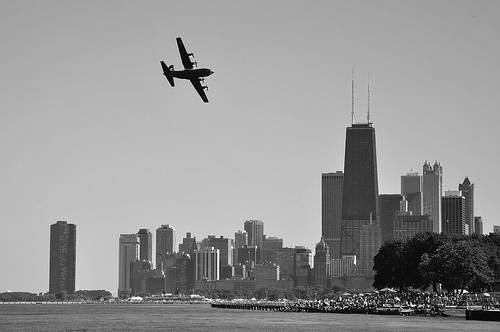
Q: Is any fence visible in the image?
A: No, there are no fences.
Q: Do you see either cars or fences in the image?
A: No, there are no fences or cars.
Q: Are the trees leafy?
A: Yes, the trees are leafy.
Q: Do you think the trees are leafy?
A: Yes, the trees are leafy.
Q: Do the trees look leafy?
A: Yes, the trees are leafy.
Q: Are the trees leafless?
A: No, the trees are leafy.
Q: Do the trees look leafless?
A: No, the trees are leafy.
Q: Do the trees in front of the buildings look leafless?
A: No, the trees are leafy.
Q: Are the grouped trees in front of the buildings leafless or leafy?
A: The trees are leafy.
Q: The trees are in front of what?
A: The trees are in front of the buildings.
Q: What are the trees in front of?
A: The trees are in front of the buildings.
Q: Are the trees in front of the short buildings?
A: Yes, the trees are in front of the buildings.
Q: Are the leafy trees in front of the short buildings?
A: Yes, the trees are in front of the buildings.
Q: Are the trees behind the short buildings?
A: No, the trees are in front of the buildings.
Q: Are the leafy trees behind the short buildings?
A: No, the trees are in front of the buildings.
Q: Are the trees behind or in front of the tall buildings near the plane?
A: The trees are in front of the buildings.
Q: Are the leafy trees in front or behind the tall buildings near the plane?
A: The trees are in front of the buildings.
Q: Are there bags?
A: No, there are no bags.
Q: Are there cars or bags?
A: No, there are no bags or cars.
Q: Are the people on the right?
A: Yes, the people are on the right of the image.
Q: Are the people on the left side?
A: No, the people are on the right of the image.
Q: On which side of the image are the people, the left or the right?
A: The people are on the right of the image.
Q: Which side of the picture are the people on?
A: The people are on the right of the image.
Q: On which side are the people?
A: The people are on the right of the image.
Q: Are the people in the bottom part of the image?
A: Yes, the people are in the bottom of the image.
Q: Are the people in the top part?
A: No, the people are in the bottom of the image.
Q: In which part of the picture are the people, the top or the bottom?
A: The people are in the bottom of the image.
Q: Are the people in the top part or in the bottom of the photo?
A: The people are in the bottom of the image.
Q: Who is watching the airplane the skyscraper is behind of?
A: The people are watching the airplane.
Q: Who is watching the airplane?
A: The people are watching the airplane.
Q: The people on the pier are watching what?
A: The people are watching the plane.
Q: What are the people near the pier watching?
A: The people are watching the plane.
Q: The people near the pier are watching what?
A: The people are watching the plane.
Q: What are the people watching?
A: The people are watching the plane.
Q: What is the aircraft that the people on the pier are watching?
A: The aircraft is an airplane.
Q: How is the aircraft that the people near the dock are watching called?
A: The aircraft is an airplane.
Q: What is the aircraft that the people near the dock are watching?
A: The aircraft is an airplane.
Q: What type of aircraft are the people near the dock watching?
A: The people are watching the airplane.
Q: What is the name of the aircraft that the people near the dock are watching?
A: The aircraft is an airplane.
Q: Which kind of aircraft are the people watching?
A: The people are watching the airplane.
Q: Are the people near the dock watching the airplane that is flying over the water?
A: Yes, the people are watching the airplane.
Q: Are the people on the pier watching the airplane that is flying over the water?
A: Yes, the people are watching the airplane.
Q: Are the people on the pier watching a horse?
A: No, the people are watching the airplane.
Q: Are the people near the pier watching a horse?
A: No, the people are watching the airplane.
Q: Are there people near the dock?
A: Yes, there are people near the dock.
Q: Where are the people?
A: The people are on the dock.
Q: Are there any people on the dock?
A: Yes, there are people on the dock.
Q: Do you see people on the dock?
A: Yes, there are people on the dock.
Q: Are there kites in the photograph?
A: No, there are no kites.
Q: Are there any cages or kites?
A: No, there are no kites or cages.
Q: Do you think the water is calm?
A: Yes, the water is calm.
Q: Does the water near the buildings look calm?
A: Yes, the water is calm.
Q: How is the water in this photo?
A: The water is calm.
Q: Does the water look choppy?
A: No, the water is calm.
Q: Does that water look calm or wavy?
A: The water is calm.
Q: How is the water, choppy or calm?
A: The water is calm.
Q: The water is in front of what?
A: The water is in front of the buildings.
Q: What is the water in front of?
A: The water is in front of the buildings.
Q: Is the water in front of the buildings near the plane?
A: Yes, the water is in front of the buildings.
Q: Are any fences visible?
A: No, there are no fences.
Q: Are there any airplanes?
A: Yes, there is an airplane.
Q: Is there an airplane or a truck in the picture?
A: Yes, there is an airplane.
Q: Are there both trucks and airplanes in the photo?
A: No, there is an airplane but no trucks.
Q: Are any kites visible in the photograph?
A: No, there are no kites.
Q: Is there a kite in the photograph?
A: No, there are no kites.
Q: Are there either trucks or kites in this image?
A: No, there are no kites or trucks.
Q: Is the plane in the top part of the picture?
A: Yes, the plane is in the top of the image.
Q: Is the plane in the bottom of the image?
A: No, the plane is in the top of the image.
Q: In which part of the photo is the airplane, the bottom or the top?
A: The airplane is in the top of the image.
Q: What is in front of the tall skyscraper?
A: The airplane is in front of the skyscraper.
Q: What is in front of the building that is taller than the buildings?
A: The airplane is in front of the skyscraper.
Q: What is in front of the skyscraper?
A: The airplane is in front of the skyscraper.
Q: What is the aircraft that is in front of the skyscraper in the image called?
A: The aircraft is an airplane.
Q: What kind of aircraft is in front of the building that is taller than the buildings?
A: The aircraft is an airplane.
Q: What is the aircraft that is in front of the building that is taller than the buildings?
A: The aircraft is an airplane.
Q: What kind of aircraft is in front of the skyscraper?
A: The aircraft is an airplane.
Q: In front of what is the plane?
A: The plane is in front of the skyscraper.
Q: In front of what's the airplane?
A: The plane is in front of the skyscraper.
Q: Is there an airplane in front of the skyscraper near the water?
A: Yes, there is an airplane in front of the skyscraper.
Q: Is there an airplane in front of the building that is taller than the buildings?
A: Yes, there is an airplane in front of the skyscraper.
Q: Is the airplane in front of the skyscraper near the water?
A: Yes, the airplane is in front of the skyscraper.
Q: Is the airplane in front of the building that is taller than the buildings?
A: Yes, the airplane is in front of the skyscraper.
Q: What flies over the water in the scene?
A: The airplane flies over the water.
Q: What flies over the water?
A: The airplane flies over the water.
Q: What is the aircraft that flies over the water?
A: The aircraft is an airplane.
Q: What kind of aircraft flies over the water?
A: The aircraft is an airplane.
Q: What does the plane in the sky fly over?
A: The plane flies over the water.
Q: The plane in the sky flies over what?
A: The plane flies over the water.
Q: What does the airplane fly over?
A: The plane flies over the water.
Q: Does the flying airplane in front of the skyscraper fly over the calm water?
A: Yes, the plane flies over the water.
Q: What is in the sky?
A: The plane is in the sky.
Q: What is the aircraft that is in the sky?
A: The aircraft is an airplane.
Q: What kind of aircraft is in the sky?
A: The aircraft is an airplane.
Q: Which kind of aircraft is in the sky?
A: The aircraft is an airplane.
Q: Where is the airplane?
A: The airplane is in the sky.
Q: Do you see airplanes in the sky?
A: Yes, there is an airplane in the sky.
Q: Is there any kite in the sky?
A: No, there is an airplane in the sky.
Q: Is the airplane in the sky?
A: Yes, the airplane is in the sky.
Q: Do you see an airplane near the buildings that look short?
A: Yes, there is an airplane near the buildings.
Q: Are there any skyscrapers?
A: Yes, there is a skyscraper.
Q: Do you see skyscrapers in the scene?
A: Yes, there is a skyscraper.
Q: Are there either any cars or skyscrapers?
A: Yes, there is a skyscraper.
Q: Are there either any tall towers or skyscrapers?
A: Yes, there is a tall skyscraper.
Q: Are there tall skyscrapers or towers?
A: Yes, there is a tall skyscraper.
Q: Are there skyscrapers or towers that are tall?
A: Yes, the skyscraper is tall.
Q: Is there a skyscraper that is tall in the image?
A: Yes, there is a tall skyscraper.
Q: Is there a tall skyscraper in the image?
A: Yes, there is a tall skyscraper.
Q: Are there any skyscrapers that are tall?
A: Yes, there is a skyscraper that is tall.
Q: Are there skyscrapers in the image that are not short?
A: Yes, there is a tall skyscraper.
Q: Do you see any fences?
A: No, there are no fences.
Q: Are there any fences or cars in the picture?
A: No, there are no fences or cars.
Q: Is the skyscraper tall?
A: Yes, the skyscraper is tall.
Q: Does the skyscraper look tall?
A: Yes, the skyscraper is tall.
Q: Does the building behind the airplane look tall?
A: Yes, the skyscraper is tall.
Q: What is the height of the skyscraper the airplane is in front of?
A: The skyscraper is tall.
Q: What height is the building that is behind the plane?
A: The skyscraper is tall.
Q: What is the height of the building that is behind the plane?
A: The skyscraper is tall.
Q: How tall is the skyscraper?
A: The skyscraper is tall.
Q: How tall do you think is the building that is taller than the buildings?
A: The skyscraper is tall.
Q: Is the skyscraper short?
A: No, the skyscraper is tall.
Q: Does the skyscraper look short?
A: No, the skyscraper is tall.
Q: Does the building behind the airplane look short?
A: No, the skyscraper is tall.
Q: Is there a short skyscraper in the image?
A: No, there is a skyscraper but it is tall.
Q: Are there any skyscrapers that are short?
A: No, there is a skyscraper but it is tall.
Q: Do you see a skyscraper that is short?
A: No, there is a skyscraper but it is tall.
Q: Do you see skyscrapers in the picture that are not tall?
A: No, there is a skyscraper but it is tall.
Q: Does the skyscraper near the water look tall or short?
A: The skyscraper is tall.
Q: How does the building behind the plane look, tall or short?
A: The skyscraper is tall.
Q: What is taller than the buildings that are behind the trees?
A: The skyscraper is taller than the buildings.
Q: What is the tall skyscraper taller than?
A: The skyscraper is taller than the buildings.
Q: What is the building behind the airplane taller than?
A: The skyscraper is taller than the buildings.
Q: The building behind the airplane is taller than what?
A: The skyscraper is taller than the buildings.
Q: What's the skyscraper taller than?
A: The skyscraper is taller than the buildings.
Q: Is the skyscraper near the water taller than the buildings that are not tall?
A: Yes, the skyscraper is taller than the buildings.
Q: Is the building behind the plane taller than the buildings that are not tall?
A: Yes, the skyscraper is taller than the buildings.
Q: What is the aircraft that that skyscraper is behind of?
A: The aircraft is an airplane.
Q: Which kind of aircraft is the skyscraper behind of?
A: The skyscraper is behind the airplane.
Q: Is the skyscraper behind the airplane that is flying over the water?
A: Yes, the skyscraper is behind the plane.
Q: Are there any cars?
A: No, there are no cars.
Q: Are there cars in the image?
A: No, there are no cars.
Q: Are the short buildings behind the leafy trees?
A: Yes, the buildings are behind the trees.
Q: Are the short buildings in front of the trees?
A: No, the buildings are behind the trees.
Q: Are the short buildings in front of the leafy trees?
A: No, the buildings are behind the trees.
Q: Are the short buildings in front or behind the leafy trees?
A: The buildings are behind the trees.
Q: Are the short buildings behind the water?
A: Yes, the buildings are behind the water.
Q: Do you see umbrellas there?
A: Yes, there are umbrellas.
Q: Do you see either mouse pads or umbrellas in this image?
A: Yes, there are umbrellas.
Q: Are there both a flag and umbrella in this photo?
A: No, there are umbrellas but no flags.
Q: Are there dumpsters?
A: No, there are no dumpsters.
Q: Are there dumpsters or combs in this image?
A: No, there are no dumpsters or combs.